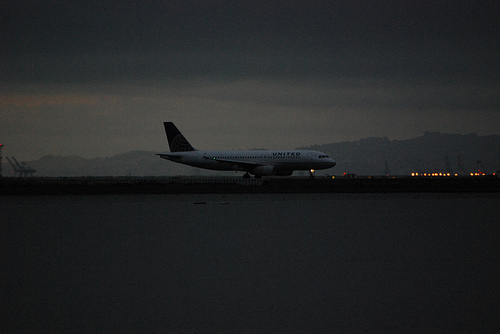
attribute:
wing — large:
[204, 153, 261, 169]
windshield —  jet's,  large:
[318, 148, 331, 163]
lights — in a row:
[418, 165, 475, 177]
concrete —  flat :
[43, 195, 499, 332]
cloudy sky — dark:
[4, 4, 496, 152]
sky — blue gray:
[1, 5, 499, 154]